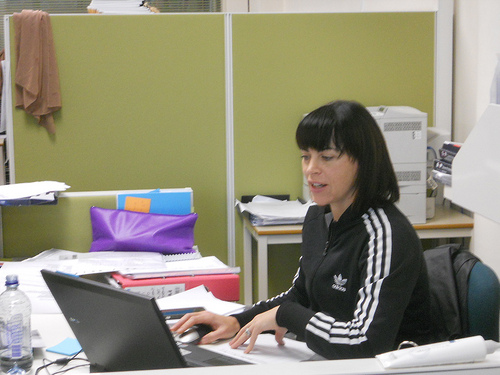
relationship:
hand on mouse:
[171, 309, 240, 344] [174, 324, 215, 344]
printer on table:
[299, 105, 428, 225] [242, 200, 476, 308]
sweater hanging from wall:
[13, 8, 64, 136] [3, 10, 441, 306]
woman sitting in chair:
[168, 98, 434, 360] [423, 245, 499, 343]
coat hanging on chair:
[423, 242, 482, 346] [423, 245, 499, 343]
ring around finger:
[245, 327, 251, 336] [231, 324, 254, 349]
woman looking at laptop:
[168, 98, 434, 360] [40, 268, 253, 373]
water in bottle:
[2, 349, 35, 374] [0, 273, 34, 374]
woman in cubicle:
[168, 98, 434, 360] [0, 11, 498, 375]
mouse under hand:
[174, 324, 215, 344] [171, 309, 240, 344]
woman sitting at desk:
[168, 98, 434, 360] [1, 184, 330, 374]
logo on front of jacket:
[330, 272, 346, 293] [229, 195, 433, 361]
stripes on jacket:
[306, 205, 392, 342] [229, 195, 433, 361]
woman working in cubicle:
[168, 98, 434, 360] [0, 11, 498, 375]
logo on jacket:
[330, 272, 346, 293] [229, 195, 433, 361]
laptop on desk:
[40, 268, 253, 373] [1, 184, 330, 374]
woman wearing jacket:
[168, 98, 434, 360] [229, 195, 433, 361]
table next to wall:
[242, 200, 476, 308] [3, 10, 441, 306]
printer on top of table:
[299, 105, 428, 225] [242, 200, 476, 308]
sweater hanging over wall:
[13, 8, 64, 136] [3, 10, 441, 306]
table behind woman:
[242, 200, 476, 308] [168, 98, 434, 360]